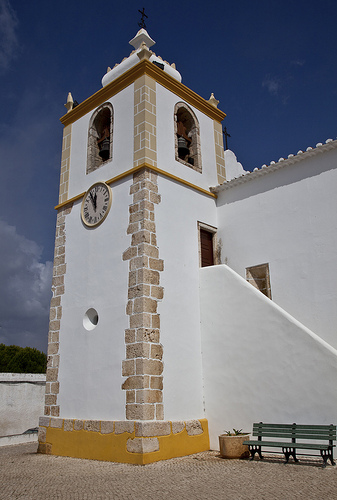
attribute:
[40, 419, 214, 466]
foundation — yellow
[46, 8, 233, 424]
tower — white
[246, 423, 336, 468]
bench — green, empty, wooden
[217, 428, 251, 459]
planter — stone, large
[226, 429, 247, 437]
plants — small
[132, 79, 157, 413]
brick — beige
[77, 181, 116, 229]
clock — beige, black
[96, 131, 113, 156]
bell — steel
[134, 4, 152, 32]
cross — black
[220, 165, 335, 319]
wall — white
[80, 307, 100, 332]
window — circular, white, round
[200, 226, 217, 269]
door — wood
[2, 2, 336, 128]
sky — blue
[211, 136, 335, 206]
roof — scalloped, white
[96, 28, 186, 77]
steeple — white